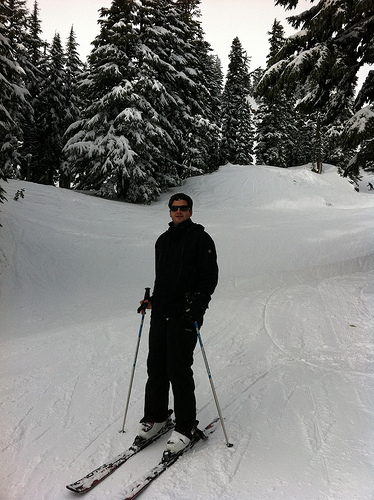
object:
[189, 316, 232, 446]
ski pole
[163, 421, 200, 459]
boots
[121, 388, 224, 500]
skis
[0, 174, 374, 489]
snow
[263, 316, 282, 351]
groove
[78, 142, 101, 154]
snow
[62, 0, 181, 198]
trees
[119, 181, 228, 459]
man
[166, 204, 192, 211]
sunglasses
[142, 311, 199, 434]
pants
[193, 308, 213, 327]
glove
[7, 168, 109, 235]
path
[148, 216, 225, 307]
coat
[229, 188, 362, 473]
slope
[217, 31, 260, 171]
evergreen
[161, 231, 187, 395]
snow gear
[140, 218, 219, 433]
clothing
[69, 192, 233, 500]
skier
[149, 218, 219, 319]
jacket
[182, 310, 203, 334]
hand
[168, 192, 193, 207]
hair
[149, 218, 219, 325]
black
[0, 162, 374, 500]
ground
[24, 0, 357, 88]
sky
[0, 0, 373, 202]
background